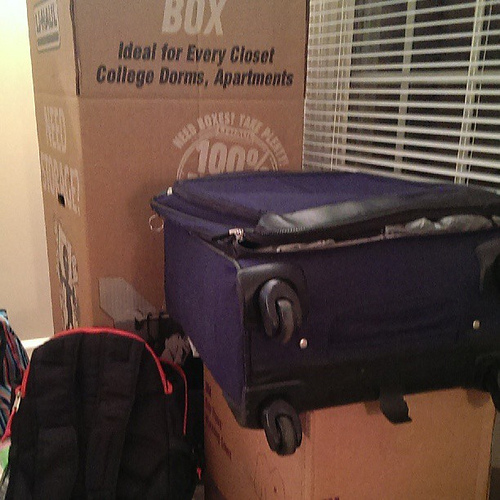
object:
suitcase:
[136, 126, 499, 456]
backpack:
[1, 318, 203, 499]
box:
[24, 8, 306, 340]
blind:
[300, 0, 499, 197]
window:
[305, 0, 500, 183]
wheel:
[261, 276, 306, 352]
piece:
[355, 178, 447, 243]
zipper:
[242, 185, 499, 240]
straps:
[24, 336, 88, 495]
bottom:
[238, 229, 496, 434]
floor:
[94, 457, 232, 491]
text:
[94, 27, 296, 97]